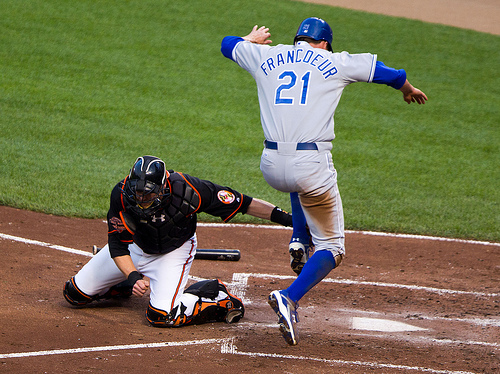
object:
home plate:
[351, 316, 429, 332]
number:
[274, 70, 312, 106]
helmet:
[293, 16, 334, 53]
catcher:
[61, 154, 296, 328]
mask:
[118, 179, 172, 219]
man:
[219, 16, 428, 347]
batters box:
[219, 272, 499, 374]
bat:
[194, 248, 241, 261]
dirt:
[0, 221, 499, 373]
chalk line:
[0, 337, 229, 360]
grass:
[0, 0, 499, 234]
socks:
[286, 249, 337, 302]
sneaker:
[210, 277, 246, 324]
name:
[260, 48, 339, 80]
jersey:
[231, 40, 378, 143]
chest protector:
[122, 168, 200, 255]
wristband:
[126, 271, 141, 289]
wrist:
[125, 270, 142, 287]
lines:
[183, 271, 282, 358]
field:
[0, 0, 499, 374]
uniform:
[219, 34, 407, 303]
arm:
[184, 174, 292, 228]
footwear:
[265, 289, 300, 346]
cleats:
[266, 293, 299, 345]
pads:
[145, 300, 235, 328]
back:
[257, 44, 344, 143]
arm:
[337, 51, 410, 92]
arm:
[220, 35, 275, 73]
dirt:
[299, 191, 336, 243]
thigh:
[298, 176, 347, 249]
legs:
[290, 182, 347, 289]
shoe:
[288, 235, 313, 277]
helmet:
[118, 155, 172, 219]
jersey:
[106, 168, 244, 258]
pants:
[62, 231, 214, 328]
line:
[0, 232, 93, 256]